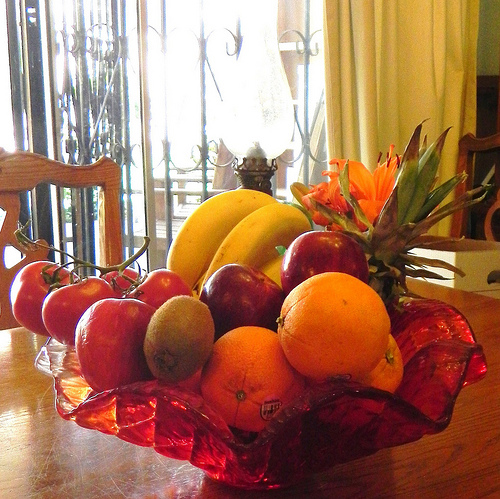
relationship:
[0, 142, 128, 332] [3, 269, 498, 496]
chair next to table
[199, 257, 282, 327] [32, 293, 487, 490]
apple in bowl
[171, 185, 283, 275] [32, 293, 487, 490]
fruit in bowl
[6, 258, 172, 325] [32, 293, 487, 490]
vegetables in bowl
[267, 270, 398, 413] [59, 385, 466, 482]
orange in bowl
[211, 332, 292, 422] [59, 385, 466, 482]
orange in bowl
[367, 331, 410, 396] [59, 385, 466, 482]
orange in bowl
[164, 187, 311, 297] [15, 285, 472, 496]
bananas in bowl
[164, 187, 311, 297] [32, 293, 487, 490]
bananas on bowl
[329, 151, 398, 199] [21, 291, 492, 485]
flower in dish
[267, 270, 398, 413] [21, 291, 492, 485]
orange in dish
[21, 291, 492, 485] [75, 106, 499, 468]
dish on table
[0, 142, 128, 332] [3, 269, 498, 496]
chair beside table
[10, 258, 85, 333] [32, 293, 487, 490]
tomatoes in bowl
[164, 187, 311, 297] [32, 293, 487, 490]
bananas in bowl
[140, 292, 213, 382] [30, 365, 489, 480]
kiwi in bowl